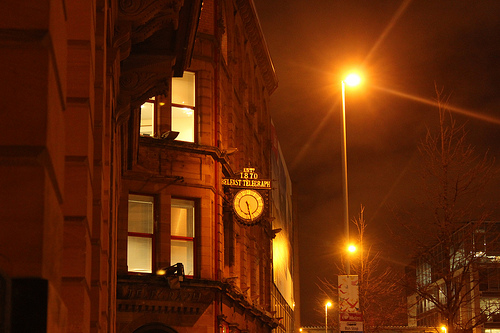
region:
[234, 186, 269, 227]
clock on side of building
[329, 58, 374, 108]
street light turned on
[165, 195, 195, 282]
window on building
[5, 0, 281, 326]
old looking building with lit windows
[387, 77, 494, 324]
large tree with no leaves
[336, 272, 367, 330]
sign on the lamp post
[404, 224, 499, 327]
building in the background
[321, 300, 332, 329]
lamp post in the background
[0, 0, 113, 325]
brick material on building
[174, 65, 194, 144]
light in the window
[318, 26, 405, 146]
a street light near a building.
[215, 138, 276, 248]
a clock on a building.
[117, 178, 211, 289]
a building window.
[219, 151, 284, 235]
a sign with a clock.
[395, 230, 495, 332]
a tall multi story building.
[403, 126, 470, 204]
a section of night sky.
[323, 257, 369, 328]
a road sign near a building.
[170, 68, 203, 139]
a second story window.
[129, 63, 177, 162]
an adjacent window on a second story.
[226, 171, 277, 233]
a clock on a sign.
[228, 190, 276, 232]
Large clock on building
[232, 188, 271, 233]
Large clock next to window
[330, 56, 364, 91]
Light is bright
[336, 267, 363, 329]
Banner on light post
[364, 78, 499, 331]
Bare tree next to light post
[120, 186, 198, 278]
Window on building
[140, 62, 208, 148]
Window on building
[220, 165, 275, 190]
Sign above white clock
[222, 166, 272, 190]
Sign attached to building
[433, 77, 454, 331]
Long bare tree branch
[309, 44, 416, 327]
street lights are on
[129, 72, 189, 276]
lights showing through windows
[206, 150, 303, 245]
clock attached to building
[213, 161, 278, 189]
letters above the clock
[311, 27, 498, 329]
trees have no leaves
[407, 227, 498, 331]
lights are on in building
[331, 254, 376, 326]
base of light is gray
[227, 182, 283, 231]
the clock is white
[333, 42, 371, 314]
the lights are orange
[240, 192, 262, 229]
clock hands are black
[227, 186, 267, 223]
large clock face on side of building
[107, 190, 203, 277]
windows on side of building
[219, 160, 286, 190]
white writing on sign above clock face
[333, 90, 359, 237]
grey metal street light pole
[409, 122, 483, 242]
tree branches with no leaves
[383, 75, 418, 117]
beam of light reflecting from street light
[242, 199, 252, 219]
large metal clock hands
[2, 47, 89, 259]
red bricks on side of building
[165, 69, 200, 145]
windows with light shining behind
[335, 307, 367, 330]
writing on side of large white building